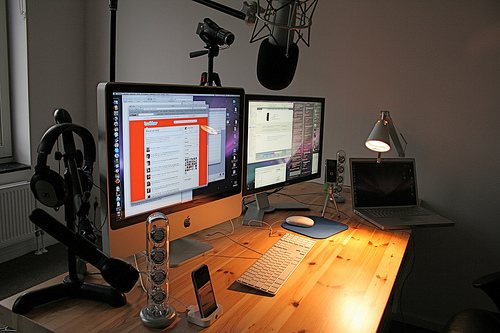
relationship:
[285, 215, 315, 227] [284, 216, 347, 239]
mouse on mousepad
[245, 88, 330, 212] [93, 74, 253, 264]
monitor next to monitor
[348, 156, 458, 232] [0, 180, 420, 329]
silver laptop hanging off desk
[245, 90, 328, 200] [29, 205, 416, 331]
monitor on a desk